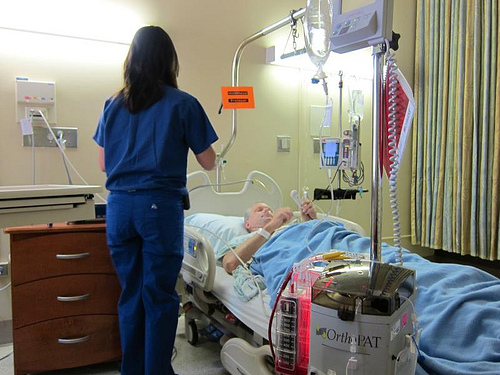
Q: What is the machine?
A: Medical equipment.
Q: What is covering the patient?
A: A blue blanket.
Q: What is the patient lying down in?
A: A bed.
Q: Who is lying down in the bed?
A: A man.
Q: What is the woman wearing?
A: Scrubs.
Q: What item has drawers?
A: A cabinet.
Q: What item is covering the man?
A: A blanket.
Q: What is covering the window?
A: A curtain.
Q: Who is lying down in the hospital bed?
A: A man.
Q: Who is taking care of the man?
A: A nurse.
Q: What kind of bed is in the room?
A: A hospital bed.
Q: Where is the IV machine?
A: Next to the bed.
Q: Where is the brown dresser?
A: Next to the bed.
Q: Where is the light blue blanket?
A: On the patient.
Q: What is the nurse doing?
A: Checking on her patient.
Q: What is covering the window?
A: A curtain.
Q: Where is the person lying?
A: In a hospital bed.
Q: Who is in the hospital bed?
A: Patient.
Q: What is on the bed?
A: Patient.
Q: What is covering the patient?
A: Blanket.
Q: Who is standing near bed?
A: Nurse.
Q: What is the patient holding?
A: Controller.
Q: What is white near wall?
A: Headboard.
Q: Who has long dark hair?
A: Nurse.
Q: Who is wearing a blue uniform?
A: Nurse.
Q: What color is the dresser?
A: Brown.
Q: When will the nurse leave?
A: When she has finished helping the patient.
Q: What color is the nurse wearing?
A: Blue.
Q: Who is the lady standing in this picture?
A: A nurse.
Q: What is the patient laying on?
A: A hospital bed.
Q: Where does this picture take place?
A: In a hospital room.